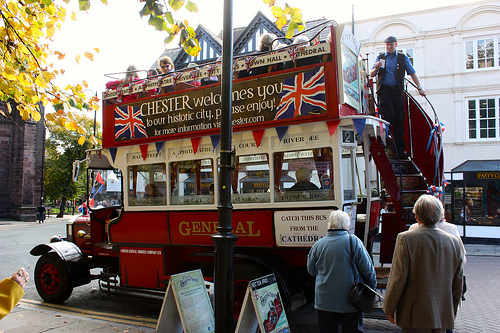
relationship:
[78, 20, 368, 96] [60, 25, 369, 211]
people sitting in bus top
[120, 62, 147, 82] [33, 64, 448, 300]
person gazing from vehicle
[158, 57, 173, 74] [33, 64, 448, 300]
passenger gazing from vehicle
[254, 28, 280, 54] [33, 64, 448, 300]
person gazing from vehicle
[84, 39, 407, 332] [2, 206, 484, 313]
bus on road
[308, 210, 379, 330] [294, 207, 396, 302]
lady has hair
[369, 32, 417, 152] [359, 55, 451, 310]
man on stairwell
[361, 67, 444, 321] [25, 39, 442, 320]
stairwell winds up bus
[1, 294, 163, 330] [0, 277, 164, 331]
lines near curb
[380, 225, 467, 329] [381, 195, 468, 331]
brown jacket worn by person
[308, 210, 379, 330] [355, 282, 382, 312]
lady has purse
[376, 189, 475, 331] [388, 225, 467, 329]
person has brown jacket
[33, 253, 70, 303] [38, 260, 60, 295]
tire has red hubcap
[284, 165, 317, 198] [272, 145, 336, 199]
man behind window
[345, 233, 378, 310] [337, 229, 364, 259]
purse on shoulder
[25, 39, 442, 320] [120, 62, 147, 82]
bus has person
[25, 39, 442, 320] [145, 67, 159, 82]
bus has passenger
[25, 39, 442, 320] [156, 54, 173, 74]
bus has passenger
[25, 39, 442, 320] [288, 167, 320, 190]
bus has man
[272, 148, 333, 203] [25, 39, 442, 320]
window on side of bus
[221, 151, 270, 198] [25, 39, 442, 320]
window on side of bus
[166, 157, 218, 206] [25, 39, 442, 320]
window on side of bus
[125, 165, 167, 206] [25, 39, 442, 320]
window on side of bus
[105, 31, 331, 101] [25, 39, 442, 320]
people on second deck of bus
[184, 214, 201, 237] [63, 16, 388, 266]
letter on bus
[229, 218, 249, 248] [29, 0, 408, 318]
letter on bus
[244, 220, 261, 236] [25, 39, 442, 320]
l on bus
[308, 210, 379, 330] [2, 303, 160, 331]
lady on sidewalk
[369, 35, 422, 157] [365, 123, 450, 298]
man on stairs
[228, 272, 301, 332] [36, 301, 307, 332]
sign on sidewalk